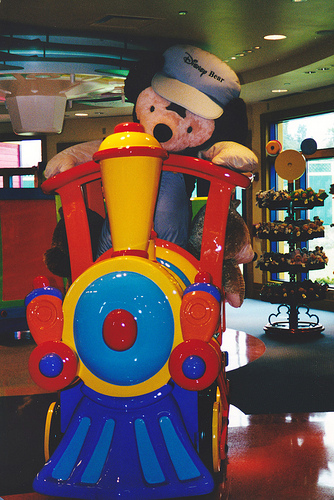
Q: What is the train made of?
A: Plastic.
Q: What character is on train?
A: Mickey Mouse.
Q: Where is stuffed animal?
A: On train.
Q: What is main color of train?
A: Red.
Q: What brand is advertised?
A: Disney.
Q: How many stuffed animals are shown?
A: One.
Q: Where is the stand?
A: On floor.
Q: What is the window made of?
A: Glass.